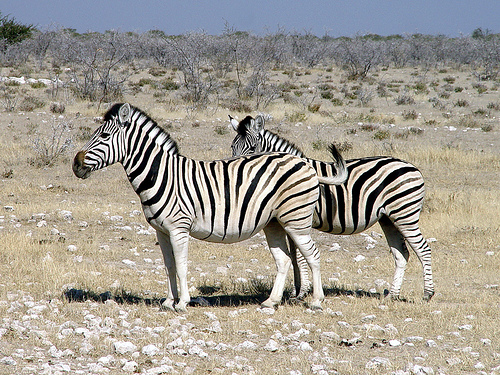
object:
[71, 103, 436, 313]
two zebras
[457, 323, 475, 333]
small rocks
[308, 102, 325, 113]
scrub brush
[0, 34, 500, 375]
ground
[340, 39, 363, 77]
bare trees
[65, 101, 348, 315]
zebra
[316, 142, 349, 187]
tail with black tip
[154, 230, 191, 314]
two front legs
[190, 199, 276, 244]
stomach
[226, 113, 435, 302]
zebra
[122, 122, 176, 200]
neck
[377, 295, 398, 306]
hoof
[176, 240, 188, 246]
faded stripes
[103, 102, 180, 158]
mane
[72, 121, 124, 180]
face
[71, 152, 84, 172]
black nose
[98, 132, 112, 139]
dark eyes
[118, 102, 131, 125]
white ears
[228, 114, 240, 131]
ear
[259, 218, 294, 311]
back two legs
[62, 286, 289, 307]
shadow